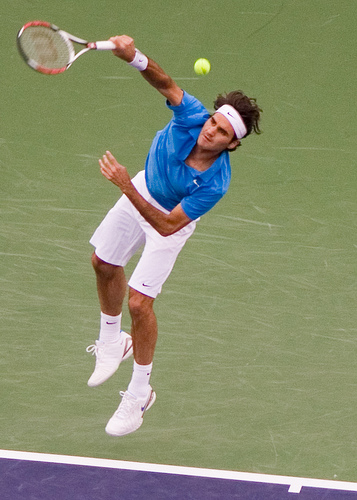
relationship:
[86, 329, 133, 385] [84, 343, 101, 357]
shoe has shoe lace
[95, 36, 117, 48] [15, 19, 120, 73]
tape on tennis racket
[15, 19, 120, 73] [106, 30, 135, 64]
tennis racket in mans hand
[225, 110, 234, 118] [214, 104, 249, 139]
nike logo on headband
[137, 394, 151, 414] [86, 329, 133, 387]
nike logo on shoe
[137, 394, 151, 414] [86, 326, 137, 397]
nike logo on white shoe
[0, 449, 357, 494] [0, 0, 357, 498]
stripe on tennis court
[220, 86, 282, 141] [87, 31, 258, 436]
hair on person